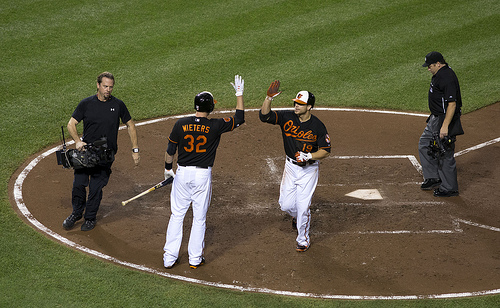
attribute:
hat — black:
[192, 95, 226, 112]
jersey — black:
[165, 111, 233, 169]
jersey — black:
[271, 107, 334, 167]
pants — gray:
[415, 110, 457, 193]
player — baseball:
[160, 72, 245, 269]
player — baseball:
[258, 78, 332, 252]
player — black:
[252, 71, 340, 261]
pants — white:
[273, 146, 325, 253]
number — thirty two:
[168, 125, 231, 159]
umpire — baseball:
[404, 53, 499, 183]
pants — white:
[162, 161, 214, 267]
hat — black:
[418, 45, 454, 74]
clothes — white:
[265, 97, 320, 250]